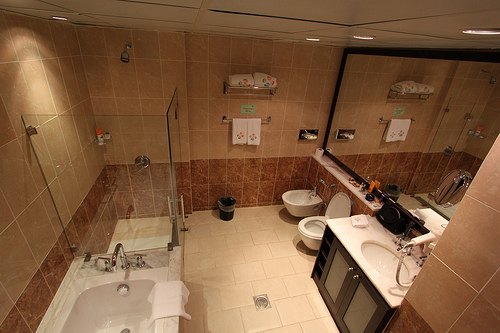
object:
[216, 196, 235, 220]
can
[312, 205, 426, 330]
vanity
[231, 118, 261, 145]
towel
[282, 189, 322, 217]
bidet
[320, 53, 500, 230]
reflection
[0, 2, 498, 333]
bathroom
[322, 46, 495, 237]
mirror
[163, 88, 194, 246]
doors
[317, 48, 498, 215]
ground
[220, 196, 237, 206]
bag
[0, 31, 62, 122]
reflection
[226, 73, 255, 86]
towel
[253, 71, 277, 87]
towel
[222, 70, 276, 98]
rack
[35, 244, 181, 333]
bathtub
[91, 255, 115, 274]
valve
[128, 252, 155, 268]
valve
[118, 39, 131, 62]
showerhead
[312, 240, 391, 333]
closed doors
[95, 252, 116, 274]
left knob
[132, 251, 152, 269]
knob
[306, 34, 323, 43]
lights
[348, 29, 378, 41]
lights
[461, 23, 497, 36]
lights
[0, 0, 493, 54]
ceiling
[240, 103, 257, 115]
sign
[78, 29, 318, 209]
wall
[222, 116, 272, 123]
rack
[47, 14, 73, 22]
light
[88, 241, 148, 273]
faucet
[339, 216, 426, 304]
sink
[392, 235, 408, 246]
left knob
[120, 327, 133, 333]
drain hole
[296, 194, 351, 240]
seat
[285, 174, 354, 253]
toilet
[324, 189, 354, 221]
cover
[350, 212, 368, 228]
wash cloth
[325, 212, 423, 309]
sink counter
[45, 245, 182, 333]
tub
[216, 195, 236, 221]
black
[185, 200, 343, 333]
floor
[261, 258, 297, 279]
tile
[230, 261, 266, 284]
tile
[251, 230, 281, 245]
tile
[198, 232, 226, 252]
tile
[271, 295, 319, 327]
tile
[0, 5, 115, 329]
wall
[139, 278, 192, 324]
towel